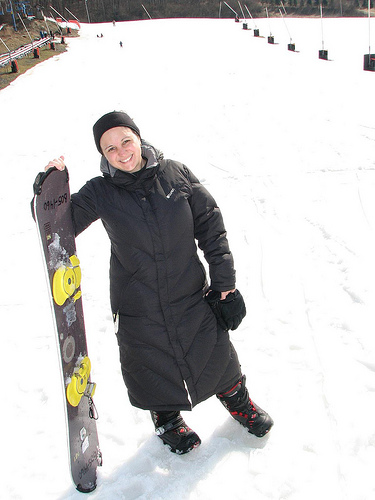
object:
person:
[30, 109, 276, 457]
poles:
[318, 0, 330, 61]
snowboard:
[34, 155, 103, 494]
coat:
[30, 139, 244, 416]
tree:
[0, 0, 36, 31]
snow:
[4, 19, 375, 499]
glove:
[207, 286, 248, 333]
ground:
[261, 64, 372, 495]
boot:
[142, 404, 202, 457]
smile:
[117, 152, 134, 164]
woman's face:
[98, 123, 142, 172]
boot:
[213, 375, 274, 439]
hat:
[91, 108, 144, 156]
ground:
[0, 19, 375, 498]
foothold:
[52, 253, 82, 307]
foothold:
[66, 349, 93, 407]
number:
[43, 192, 68, 211]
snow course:
[0, 15, 371, 156]